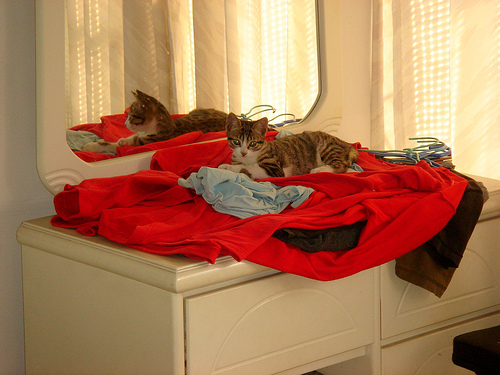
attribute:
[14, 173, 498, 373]
dresser — white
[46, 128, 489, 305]
clothing — red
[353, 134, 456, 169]
hangers — blue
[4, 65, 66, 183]
wall — grey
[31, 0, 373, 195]
frame — white , thick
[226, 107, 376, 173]
cat — striped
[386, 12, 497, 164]
curtains — tan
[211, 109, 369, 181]
cat — laying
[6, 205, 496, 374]
dresser — white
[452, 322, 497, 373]
stool — black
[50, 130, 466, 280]
fabric — bright orange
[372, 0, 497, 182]
curtain — light-colored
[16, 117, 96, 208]
frame — white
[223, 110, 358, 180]
kitten — grey, white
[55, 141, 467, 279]
blanket — red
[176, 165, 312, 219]
cloth — blue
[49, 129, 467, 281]
blanket — red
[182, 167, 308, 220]
clothing — blue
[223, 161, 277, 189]
paw — white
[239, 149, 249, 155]
nose — pink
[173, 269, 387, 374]
drawer — white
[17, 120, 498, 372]
dresser — white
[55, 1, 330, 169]
mirror — framed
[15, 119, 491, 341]
dresser — off white